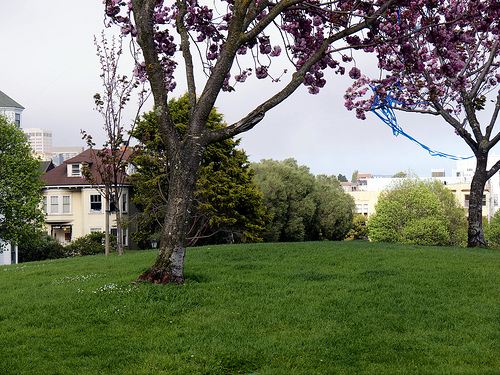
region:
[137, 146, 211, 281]
the trunk of a tree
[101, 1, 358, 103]
a pink flowering tree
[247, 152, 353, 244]
green trees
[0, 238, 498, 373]
a green grassy lawn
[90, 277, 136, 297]
white flowers in the grass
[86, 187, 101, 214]
a window on the house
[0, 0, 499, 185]
a gray sky overhead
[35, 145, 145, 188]
a brown roof on the house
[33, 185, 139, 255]
a cream colored house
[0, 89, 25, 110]
a gray roof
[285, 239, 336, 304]
part of a green ground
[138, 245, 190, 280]
base of a tree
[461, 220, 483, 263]
part of a tree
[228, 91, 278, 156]
part of a branch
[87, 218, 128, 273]
part of a post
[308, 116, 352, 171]
part of the sky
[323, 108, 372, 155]
part of the sky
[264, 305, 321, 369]
part of a ground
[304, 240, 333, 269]
part of a green ground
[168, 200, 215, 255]
stem of a tree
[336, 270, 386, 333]
part of a green ground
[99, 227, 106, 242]
part of a post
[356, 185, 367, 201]
part of a building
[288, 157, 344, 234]
edge of a bush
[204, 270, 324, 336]
The grass is green.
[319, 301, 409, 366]
The grass is green.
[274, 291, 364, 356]
The grass is green.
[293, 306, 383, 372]
The grass is green.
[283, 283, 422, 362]
The grass is green.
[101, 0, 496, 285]
purple blossoms on two big trees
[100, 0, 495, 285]
two trees with purple flowers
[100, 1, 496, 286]
purple flowers on two trees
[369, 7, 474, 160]
blue kite twine in the tree limbs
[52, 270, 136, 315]
small white flowers in the green grass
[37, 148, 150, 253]
two story light yellow house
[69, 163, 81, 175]
window on the roof to the attic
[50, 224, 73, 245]
back porch to the house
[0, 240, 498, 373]
green lawn containing trees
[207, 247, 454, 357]
green grass on the lawn